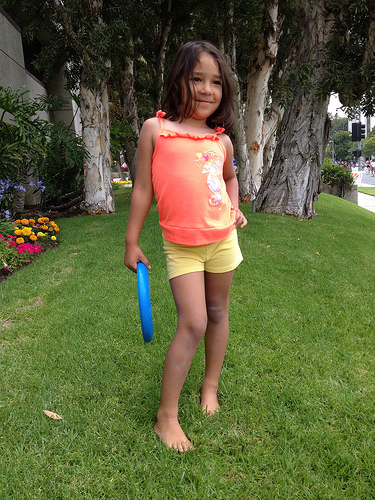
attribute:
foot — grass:
[197, 375, 222, 416]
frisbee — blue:
[113, 254, 186, 337]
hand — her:
[70, 220, 173, 253]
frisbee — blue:
[120, 249, 170, 354]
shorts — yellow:
[131, 212, 284, 285]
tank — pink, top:
[151, 118, 242, 246]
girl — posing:
[118, 37, 259, 448]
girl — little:
[123, 37, 251, 457]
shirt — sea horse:
[152, 110, 235, 240]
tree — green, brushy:
[48, 1, 123, 216]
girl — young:
[116, 40, 281, 463]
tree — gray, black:
[250, 0, 345, 210]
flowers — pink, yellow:
[5, 198, 65, 265]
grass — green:
[3, 199, 374, 496]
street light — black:
[353, 116, 367, 148]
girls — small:
[157, 33, 257, 456]